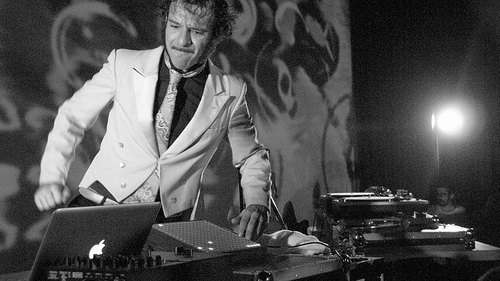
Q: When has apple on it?
A: Laptop.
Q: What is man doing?
A: Playing music.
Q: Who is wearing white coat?
A: Dj.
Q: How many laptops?
A: One.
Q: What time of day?
A: Night.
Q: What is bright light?
A: Light on pole.